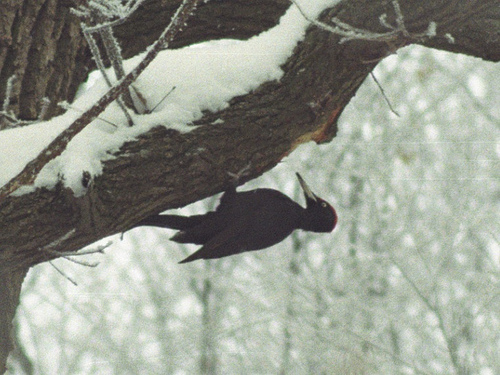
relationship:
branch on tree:
[48, 226, 78, 251] [7, 0, 490, 367]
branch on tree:
[46, 238, 118, 262] [7, 0, 490, 367]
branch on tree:
[46, 254, 78, 289] [7, 0, 490, 367]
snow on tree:
[0, 0, 340, 198] [3, 2, 498, 299]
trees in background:
[11, 2, 498, 364] [18, 58, 482, 360]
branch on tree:
[292, 2, 402, 39] [7, 0, 490, 367]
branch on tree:
[402, 21, 465, 40] [7, 0, 490, 367]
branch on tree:
[367, 68, 402, 119] [7, 0, 490, 367]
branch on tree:
[37, 230, 114, 285] [7, 0, 490, 367]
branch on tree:
[74, 4, 176, 122] [7, 0, 490, 367]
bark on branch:
[110, 101, 330, 208] [24, 1, 481, 271]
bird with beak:
[133, 170, 337, 263] [298, 167, 318, 202]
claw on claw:
[235, 161, 250, 178] [227, 159, 253, 180]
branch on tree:
[403, 21, 438, 40] [7, 0, 490, 367]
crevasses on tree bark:
[119, 129, 273, 160] [0, 5, 494, 245]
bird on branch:
[120, 159, 337, 264] [0, 7, 499, 271]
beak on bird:
[290, 165, 345, 232] [120, 159, 337, 264]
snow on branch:
[9, 27, 306, 175] [8, 2, 492, 200]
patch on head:
[330, 211, 339, 223] [290, 170, 351, 245]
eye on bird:
[321, 200, 328, 207] [176, 172, 340, 262]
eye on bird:
[321, 202, 327, 208] [120, 159, 337, 264]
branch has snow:
[0, 16, 419, 258] [9, 18, 284, 170]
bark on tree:
[1, 3, 498, 340] [7, 0, 490, 367]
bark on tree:
[0, 1, 84, 122] [10, 4, 498, 270]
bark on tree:
[118, 135, 195, 184] [7, 0, 490, 367]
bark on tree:
[25, 2, 55, 116] [7, 0, 490, 367]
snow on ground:
[183, 62, 258, 81] [67, 25, 286, 142]